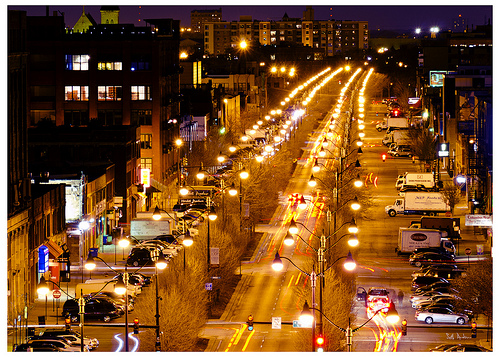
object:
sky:
[15, 5, 499, 39]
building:
[201, 14, 372, 64]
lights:
[235, 38, 252, 52]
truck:
[383, 187, 452, 216]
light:
[392, 110, 400, 118]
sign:
[132, 217, 179, 237]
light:
[220, 127, 228, 134]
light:
[356, 140, 364, 147]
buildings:
[24, 37, 211, 178]